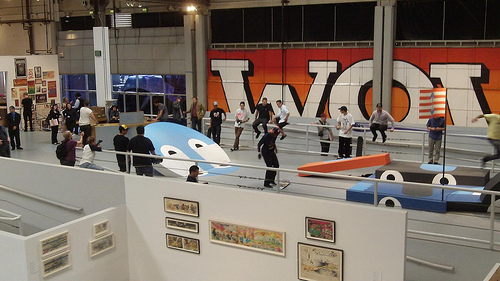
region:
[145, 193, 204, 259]
three pictures on the wall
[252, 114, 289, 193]
person skateboarding near the ramps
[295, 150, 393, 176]
orange ramp on the ground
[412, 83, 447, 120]
flag on a pole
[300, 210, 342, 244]
small picture on the wall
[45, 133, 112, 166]
people looking over the railing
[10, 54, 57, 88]
several pictures on the wall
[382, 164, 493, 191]
ramp that looks like a car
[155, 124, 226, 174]
blue and white ramp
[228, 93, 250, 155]
person leaning on the railing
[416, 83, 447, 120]
Orange and white striped flag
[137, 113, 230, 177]
Blue and white face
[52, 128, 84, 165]
Person wearing a black backpack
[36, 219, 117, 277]
Four pictures in white picture frames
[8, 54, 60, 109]
Signs on a white wall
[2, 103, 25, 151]
Man wearing a black suit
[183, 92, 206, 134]
Man in a tan jacket and blue jeans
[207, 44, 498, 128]
Red and orange painted wall with white letters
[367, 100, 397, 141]
Man sitting on a railing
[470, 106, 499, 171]
Man jumping across objects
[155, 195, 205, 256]
pictures on the wall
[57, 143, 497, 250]
Railing on the floor.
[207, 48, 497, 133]
Orange coloring on the wall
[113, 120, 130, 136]
man wearing a hat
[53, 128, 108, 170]
people leaning on the railing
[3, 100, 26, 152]
man in a suit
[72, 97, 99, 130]
white shirt on the person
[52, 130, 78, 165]
black backpack on the person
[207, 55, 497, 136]
white lettering on the wall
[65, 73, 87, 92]
Window in the room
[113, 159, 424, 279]
a white wall partition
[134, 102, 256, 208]
blue object attached to the floor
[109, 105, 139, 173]
this is a person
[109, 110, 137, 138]
person wearing a hat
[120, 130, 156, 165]
man wearing a black shirt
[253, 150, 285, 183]
man wearing black pants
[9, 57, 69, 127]
pictures is on a wall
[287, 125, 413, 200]
orange block on the floor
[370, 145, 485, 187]
black block on floor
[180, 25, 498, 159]
orange and white wall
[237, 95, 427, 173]
three boys sitting on a railing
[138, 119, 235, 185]
a round blue and white ramp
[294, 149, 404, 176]
an orange ramp resting on black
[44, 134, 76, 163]
a black backpack on back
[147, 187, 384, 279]
several pictures on a wall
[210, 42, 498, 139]
an orange wall with white letters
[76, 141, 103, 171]
a white shirt with black sleeves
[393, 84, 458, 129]
an orange and white flag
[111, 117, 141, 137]
a yellow and black hat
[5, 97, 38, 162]
a man in a suit